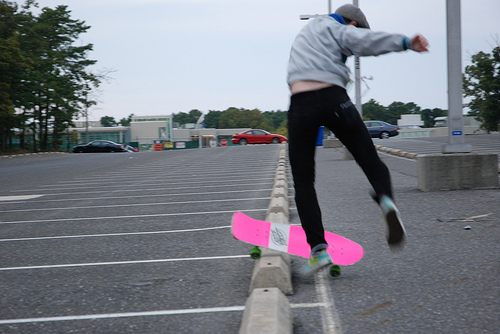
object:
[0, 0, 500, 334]
outdoors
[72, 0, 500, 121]
sky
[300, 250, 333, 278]
shoe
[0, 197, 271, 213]
line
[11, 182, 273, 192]
line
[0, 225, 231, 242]
line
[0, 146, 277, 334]
parking spots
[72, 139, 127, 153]
car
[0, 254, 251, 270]
line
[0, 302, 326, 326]
line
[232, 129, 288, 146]
pavement car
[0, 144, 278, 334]
pavement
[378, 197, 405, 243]
shoe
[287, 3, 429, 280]
skater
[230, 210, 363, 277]
skateboard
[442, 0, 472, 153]
concrete pole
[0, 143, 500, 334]
parking lot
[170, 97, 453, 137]
trees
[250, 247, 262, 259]
green wheel